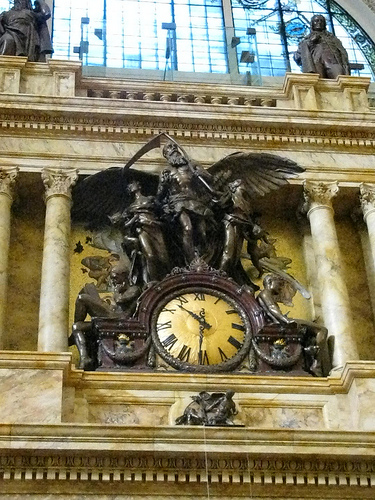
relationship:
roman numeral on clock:
[217, 345, 231, 364] [82, 143, 331, 374]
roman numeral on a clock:
[171, 341, 194, 364] [152, 289, 243, 369]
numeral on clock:
[192, 288, 206, 302] [143, 276, 260, 372]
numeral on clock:
[193, 349, 212, 365] [147, 287, 249, 366]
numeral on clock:
[159, 332, 180, 349] [148, 285, 252, 371]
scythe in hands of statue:
[121, 129, 215, 193] [160, 139, 222, 258]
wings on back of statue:
[64, 150, 310, 224] [72, 139, 305, 263]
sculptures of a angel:
[67, 132, 332, 379] [71, 130, 306, 270]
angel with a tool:
[71, 130, 306, 270] [118, 129, 220, 200]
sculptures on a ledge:
[67, 132, 332, 379] [12, 345, 350, 399]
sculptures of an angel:
[67, 132, 332, 379] [78, 130, 307, 258]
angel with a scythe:
[78, 130, 307, 258] [112, 124, 219, 194]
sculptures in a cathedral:
[67, 132, 332, 379] [10, 8, 363, 487]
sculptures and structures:
[67, 132, 332, 379] [70, 129, 333, 381]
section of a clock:
[200, 288, 253, 371] [141, 282, 253, 367]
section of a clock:
[148, 285, 200, 369] [148, 285, 252, 371]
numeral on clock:
[216, 297, 222, 306] [157, 290, 247, 368]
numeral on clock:
[224, 307, 236, 314] [156, 288, 250, 373]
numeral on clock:
[232, 324, 245, 332] [157, 290, 247, 368]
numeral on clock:
[226, 333, 242, 350] [156, 288, 250, 373]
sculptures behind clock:
[67, 132, 332, 379] [135, 285, 281, 377]